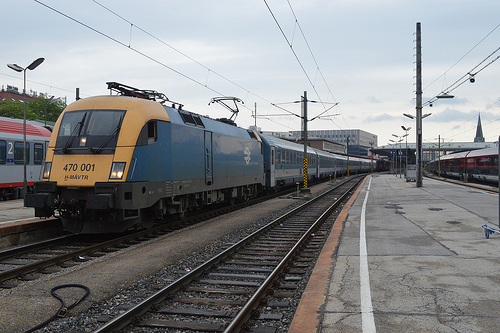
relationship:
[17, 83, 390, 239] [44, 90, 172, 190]
train front yellow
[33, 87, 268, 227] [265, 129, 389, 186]
train engine pulling cars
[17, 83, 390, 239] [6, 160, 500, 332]
trains instation station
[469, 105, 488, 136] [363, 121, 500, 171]
steeple behind station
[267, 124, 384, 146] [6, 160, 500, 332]
building near station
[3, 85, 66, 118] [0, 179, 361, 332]
foliage near tracks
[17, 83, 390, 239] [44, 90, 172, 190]
train face yellow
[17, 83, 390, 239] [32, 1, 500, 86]
train has electrical lines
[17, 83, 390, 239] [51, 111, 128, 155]
train has windows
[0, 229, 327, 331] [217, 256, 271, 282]
track has wood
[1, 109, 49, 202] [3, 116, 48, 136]
train top red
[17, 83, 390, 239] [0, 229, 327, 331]
trains on track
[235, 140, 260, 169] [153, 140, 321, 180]
logo on side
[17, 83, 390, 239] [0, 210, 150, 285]
train on track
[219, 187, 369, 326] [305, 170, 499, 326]
tracks next platform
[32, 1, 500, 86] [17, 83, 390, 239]
wires above train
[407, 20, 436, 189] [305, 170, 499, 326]
pole in platform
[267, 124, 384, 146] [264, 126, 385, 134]
building has flat roof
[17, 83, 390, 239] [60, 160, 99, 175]
train front numbers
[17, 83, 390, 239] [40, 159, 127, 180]
train has light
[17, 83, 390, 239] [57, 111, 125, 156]
train has windshield wipers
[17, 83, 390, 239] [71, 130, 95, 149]
train has headlight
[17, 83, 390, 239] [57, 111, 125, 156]
train front windhshield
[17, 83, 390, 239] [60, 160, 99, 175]
train numbers 470 001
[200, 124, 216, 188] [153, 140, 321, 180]
door on side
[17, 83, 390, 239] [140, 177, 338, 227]
train has wheel section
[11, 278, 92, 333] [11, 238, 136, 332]
cable on ground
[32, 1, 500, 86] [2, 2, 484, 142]
wires in sky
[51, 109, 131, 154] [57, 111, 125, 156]
windows have wipers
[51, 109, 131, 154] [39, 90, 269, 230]
windows of engine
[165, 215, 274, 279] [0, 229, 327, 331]
gravel between tracks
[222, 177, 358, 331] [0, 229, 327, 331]
railing of tracks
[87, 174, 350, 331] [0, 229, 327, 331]
railing of tracks